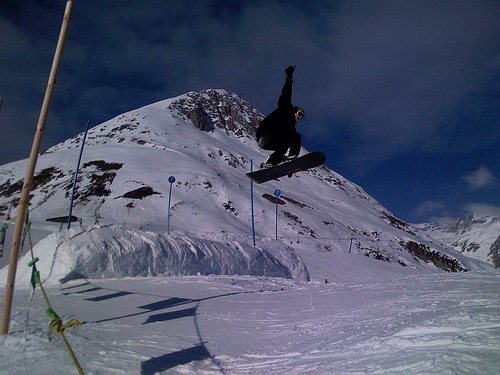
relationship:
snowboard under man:
[248, 155, 327, 185] [254, 60, 313, 150]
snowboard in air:
[248, 155, 327, 185] [312, 129, 336, 151]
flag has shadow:
[46, 309, 61, 328] [143, 301, 187, 327]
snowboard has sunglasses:
[245, 151, 328, 185] [293, 103, 311, 118]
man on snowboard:
[254, 60, 313, 150] [248, 155, 327, 185]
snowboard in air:
[245, 151, 328, 185] [312, 129, 336, 151]